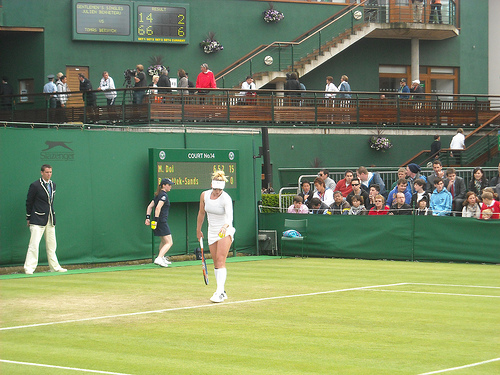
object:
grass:
[0, 253, 500, 375]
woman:
[144, 178, 175, 267]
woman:
[368, 194, 391, 215]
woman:
[466, 167, 489, 195]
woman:
[325, 76, 340, 124]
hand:
[217, 227, 226, 238]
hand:
[449, 180, 455, 185]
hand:
[482, 215, 490, 220]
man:
[196, 63, 219, 106]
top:
[196, 69, 217, 92]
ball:
[219, 232, 226, 238]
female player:
[196, 170, 236, 303]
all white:
[203, 180, 236, 246]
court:
[0, 252, 500, 375]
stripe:
[359, 282, 500, 298]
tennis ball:
[150, 220, 157, 224]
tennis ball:
[150, 225, 156, 230]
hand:
[145, 219, 151, 226]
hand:
[26, 220, 30, 227]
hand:
[97, 87, 101, 90]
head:
[210, 171, 225, 196]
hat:
[160, 177, 176, 185]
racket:
[198, 232, 209, 286]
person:
[428, 177, 453, 215]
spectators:
[287, 160, 500, 220]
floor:
[205, 136, 274, 197]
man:
[23, 163, 68, 275]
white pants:
[23, 214, 62, 274]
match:
[195, 170, 236, 304]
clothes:
[204, 189, 237, 246]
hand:
[197, 231, 204, 242]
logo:
[40, 140, 76, 162]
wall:
[0, 124, 483, 267]